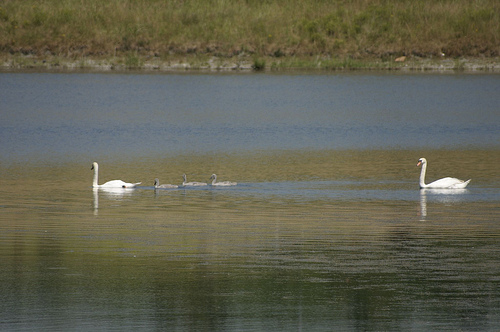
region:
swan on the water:
[404, 137, 496, 236]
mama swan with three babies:
[79, 148, 262, 223]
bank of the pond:
[6, 13, 496, 90]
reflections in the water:
[131, 227, 451, 315]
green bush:
[248, 53, 273, 76]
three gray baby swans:
[152, 166, 237, 204]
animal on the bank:
[386, 43, 421, 72]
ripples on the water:
[362, 238, 469, 328]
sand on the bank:
[62, 59, 257, 79]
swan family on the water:
[60, 141, 490, 282]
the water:
[192, 237, 267, 325]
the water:
[256, 264, 334, 329]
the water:
[205, 201, 295, 322]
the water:
[223, 241, 307, 311]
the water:
[200, 183, 282, 278]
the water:
[234, 211, 318, 328]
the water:
[265, 237, 326, 301]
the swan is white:
[410, 148, 495, 275]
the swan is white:
[353, 75, 490, 205]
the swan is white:
[373, 64, 462, 297]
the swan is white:
[378, 156, 430, 219]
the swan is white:
[398, 109, 460, 275]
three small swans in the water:
[143, 165, 236, 198]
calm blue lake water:
[120, 79, 321, 151]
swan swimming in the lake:
[411, 151, 472, 203]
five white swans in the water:
[80, 147, 497, 210]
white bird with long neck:
[407, 146, 478, 203]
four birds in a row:
[79, 144, 247, 201]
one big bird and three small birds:
[77, 149, 243, 204]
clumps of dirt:
[87, 19, 335, 56]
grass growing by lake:
[131, 4, 365, 63]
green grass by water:
[253, 46, 403, 79]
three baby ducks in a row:
[149, 171, 235, 196]